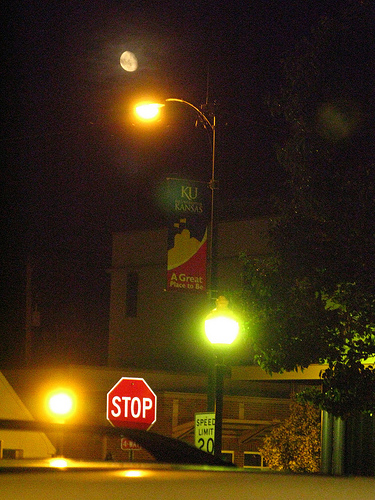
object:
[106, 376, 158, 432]
sign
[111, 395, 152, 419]
stop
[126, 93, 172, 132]
light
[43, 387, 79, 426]
light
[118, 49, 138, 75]
moon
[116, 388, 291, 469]
wall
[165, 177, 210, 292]
poster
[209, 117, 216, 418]
pole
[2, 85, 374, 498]
city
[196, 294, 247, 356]
lamp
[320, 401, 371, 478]
planter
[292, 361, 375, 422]
plant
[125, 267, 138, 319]
window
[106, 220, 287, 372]
building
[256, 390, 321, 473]
shrub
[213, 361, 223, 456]
pole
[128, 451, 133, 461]
pole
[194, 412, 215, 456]
sign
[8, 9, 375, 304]
sky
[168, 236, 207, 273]
swirl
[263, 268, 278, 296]
leaves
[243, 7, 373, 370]
tree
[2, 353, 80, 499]
street corner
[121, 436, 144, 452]
sign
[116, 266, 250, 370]
wall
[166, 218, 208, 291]
advertisement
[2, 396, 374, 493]
street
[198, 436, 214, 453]
speed limit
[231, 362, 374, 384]
awning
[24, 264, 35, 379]
pole